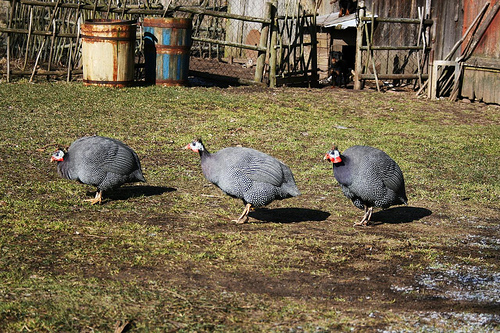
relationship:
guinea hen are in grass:
[324, 140, 406, 222] [2, 82, 498, 330]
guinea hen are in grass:
[192, 133, 302, 216] [2, 82, 498, 330]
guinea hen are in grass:
[49, 134, 145, 207] [2, 82, 498, 330]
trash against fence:
[144, 17, 191, 86] [0, 0, 277, 88]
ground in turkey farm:
[114, 248, 224, 303] [2, 0, 499, 332]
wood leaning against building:
[424, 7, 496, 131] [435, 2, 496, 110]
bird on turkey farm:
[40, 131, 152, 207] [2, 0, 499, 332]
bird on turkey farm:
[179, 132, 304, 230] [2, 0, 499, 332]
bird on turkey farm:
[317, 140, 409, 231] [2, 0, 499, 332]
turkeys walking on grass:
[46, 129, 153, 211] [10, 95, 484, 326]